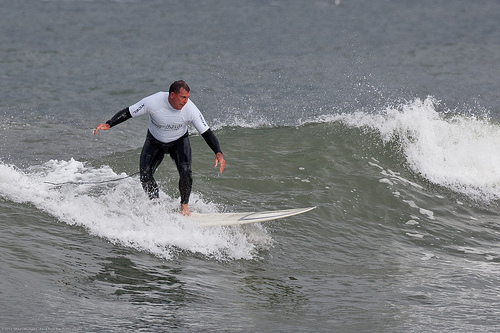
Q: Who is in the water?
A: A man.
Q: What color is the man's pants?
A: Black.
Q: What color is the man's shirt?
A: White.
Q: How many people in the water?
A: One.